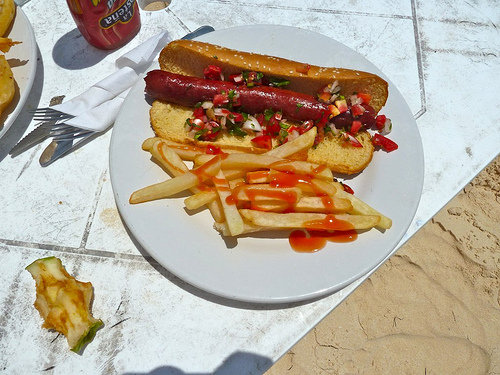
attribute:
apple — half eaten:
[24, 256, 106, 350]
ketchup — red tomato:
[194, 138, 360, 259]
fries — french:
[123, 116, 395, 256]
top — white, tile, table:
[2, 4, 495, 372]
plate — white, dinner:
[111, 22, 423, 311]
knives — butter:
[14, 98, 87, 177]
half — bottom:
[61, 0, 151, 53]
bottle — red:
[64, 2, 141, 57]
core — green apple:
[23, 254, 116, 354]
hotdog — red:
[138, 68, 417, 135]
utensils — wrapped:
[2, 25, 225, 170]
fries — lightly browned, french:
[124, 129, 394, 260]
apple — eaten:
[16, 257, 112, 358]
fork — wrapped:
[29, 100, 91, 155]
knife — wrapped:
[5, 113, 86, 175]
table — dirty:
[2, 0, 498, 371]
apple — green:
[17, 250, 110, 360]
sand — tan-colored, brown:
[264, 155, 496, 373]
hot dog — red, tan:
[144, 68, 372, 133]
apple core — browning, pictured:
[22, 252, 109, 354]